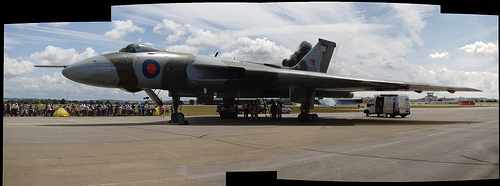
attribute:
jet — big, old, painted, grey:
[46, 40, 477, 133]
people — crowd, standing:
[8, 97, 174, 117]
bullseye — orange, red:
[137, 60, 163, 79]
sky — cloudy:
[142, 11, 485, 43]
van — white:
[366, 93, 414, 118]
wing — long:
[248, 37, 495, 109]